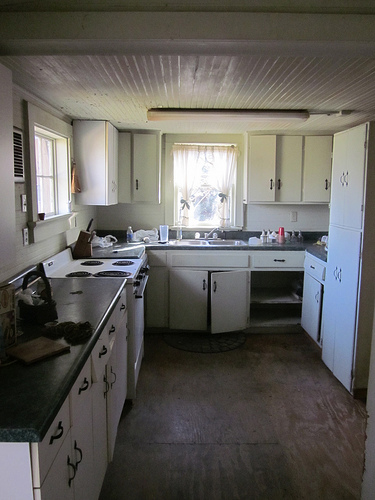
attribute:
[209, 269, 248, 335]
cabinet — white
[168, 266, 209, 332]
cabinet — white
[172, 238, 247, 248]
sink — metal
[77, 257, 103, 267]
burner — black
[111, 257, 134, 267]
burner — black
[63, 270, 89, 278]
burner — black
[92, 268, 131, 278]
burner — black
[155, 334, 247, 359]
rug — black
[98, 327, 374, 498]
floor — wooden, dark brown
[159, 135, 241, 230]
frame — white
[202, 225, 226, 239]
faucet — long, silver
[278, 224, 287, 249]
cups — stacked, red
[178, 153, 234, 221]
curtains — white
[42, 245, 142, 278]
stove top — white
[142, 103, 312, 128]
light — long, mounted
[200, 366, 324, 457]
floor — wood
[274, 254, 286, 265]
handle — black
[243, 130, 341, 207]
cabinets — white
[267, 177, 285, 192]
handles — black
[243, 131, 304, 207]
cupboards — white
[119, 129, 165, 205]
cupboards — white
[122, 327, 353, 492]
floor — wooden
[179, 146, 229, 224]
curtains — white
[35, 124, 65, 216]
window — white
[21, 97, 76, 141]
frame — white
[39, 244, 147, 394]
stove — white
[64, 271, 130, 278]
heating element — black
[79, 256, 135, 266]
heating element — black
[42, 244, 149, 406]
stove — black, white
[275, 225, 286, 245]
container — red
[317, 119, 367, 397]
cabinet — tall, white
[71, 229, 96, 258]
block — wooden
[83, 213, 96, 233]
knife — black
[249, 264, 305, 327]
cabinet — open, dark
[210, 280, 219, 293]
handle — black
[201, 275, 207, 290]
handle — black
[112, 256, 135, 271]
jet — small, black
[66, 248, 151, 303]
stove — black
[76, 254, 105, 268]
jet — small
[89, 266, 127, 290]
jet — black, large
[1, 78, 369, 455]
kitchen — white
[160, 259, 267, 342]
cabinet — open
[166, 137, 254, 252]
curtain — white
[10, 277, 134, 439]
counter — black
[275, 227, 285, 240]
cups — red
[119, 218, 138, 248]
bottle — clear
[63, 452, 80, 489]
handle — black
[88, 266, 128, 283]
burner — black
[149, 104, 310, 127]
light — large, long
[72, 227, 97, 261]
block — small, wooden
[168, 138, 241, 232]
curtains — clear, cream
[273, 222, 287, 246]
cups — red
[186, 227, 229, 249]
faucet — silver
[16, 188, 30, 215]
switch — white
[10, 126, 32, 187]
vent — silver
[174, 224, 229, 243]
sink — silver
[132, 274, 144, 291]
knob — black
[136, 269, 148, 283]
knob — black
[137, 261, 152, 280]
knob — black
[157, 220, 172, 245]
cup — clear